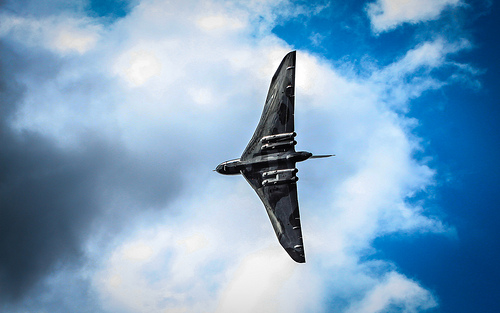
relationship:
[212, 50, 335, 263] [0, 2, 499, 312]
jet in sky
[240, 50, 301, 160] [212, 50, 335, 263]
wing of jet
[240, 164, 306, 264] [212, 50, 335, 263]
wing of jet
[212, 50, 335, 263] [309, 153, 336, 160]
jet has tail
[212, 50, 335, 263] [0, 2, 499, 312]
jet soaring through sky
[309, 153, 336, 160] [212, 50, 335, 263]
tail of jet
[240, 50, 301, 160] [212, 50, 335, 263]
wing on jet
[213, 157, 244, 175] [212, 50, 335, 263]
nose of jet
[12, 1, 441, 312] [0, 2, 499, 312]
cloud in sky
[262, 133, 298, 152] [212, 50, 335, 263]
engine on jet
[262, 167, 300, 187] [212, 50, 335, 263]
engine on jet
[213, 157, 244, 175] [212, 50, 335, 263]
nose on jet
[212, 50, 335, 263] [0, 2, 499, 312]
jet flying in sky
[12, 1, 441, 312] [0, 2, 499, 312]
cloud covering sky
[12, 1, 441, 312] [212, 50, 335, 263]
cloud behind jet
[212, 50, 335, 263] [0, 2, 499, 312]
jet flying through sky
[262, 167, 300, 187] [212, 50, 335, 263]
engine in jet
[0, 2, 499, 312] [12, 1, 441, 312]
sky has cloud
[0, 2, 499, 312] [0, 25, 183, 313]
sky has cloud